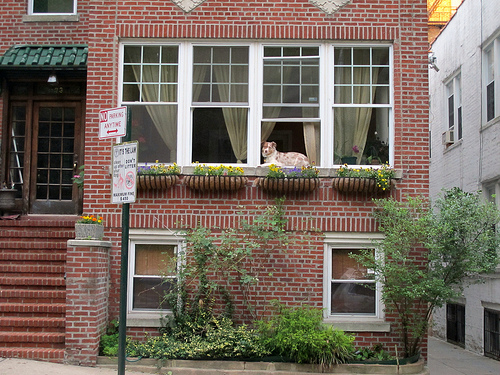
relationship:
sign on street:
[102, 106, 136, 373] [1, 358, 180, 374]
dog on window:
[262, 139, 307, 167] [263, 56, 320, 168]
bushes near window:
[177, 207, 328, 355] [263, 56, 320, 168]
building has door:
[6, 9, 430, 369] [26, 106, 72, 211]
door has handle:
[26, 106, 72, 211] [67, 154, 80, 186]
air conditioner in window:
[438, 119, 452, 153] [429, 74, 461, 149]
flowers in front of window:
[253, 170, 327, 194] [263, 56, 320, 168]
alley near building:
[409, 332, 493, 374] [6, 9, 430, 369]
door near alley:
[452, 295, 466, 355] [409, 332, 493, 374]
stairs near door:
[2, 217, 62, 363] [26, 106, 72, 211]